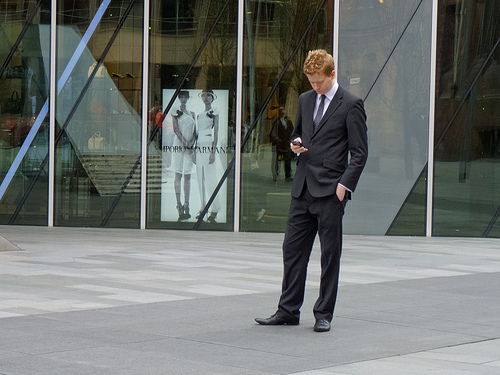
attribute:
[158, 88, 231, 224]
advertisement — large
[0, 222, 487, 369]
sidewalk — concrete slabs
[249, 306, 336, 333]
shoes — black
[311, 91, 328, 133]
tie — blue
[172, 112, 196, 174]
dress — white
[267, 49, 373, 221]
man — looking down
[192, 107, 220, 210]
suit — white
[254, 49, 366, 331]
man — suited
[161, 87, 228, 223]
ad — Emporio Armani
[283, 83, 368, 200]
jacket — black, blazer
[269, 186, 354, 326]
pants — black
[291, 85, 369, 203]
suit jacket — buttoned-up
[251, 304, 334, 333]
dress shoes — black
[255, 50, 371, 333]
boy — blonde